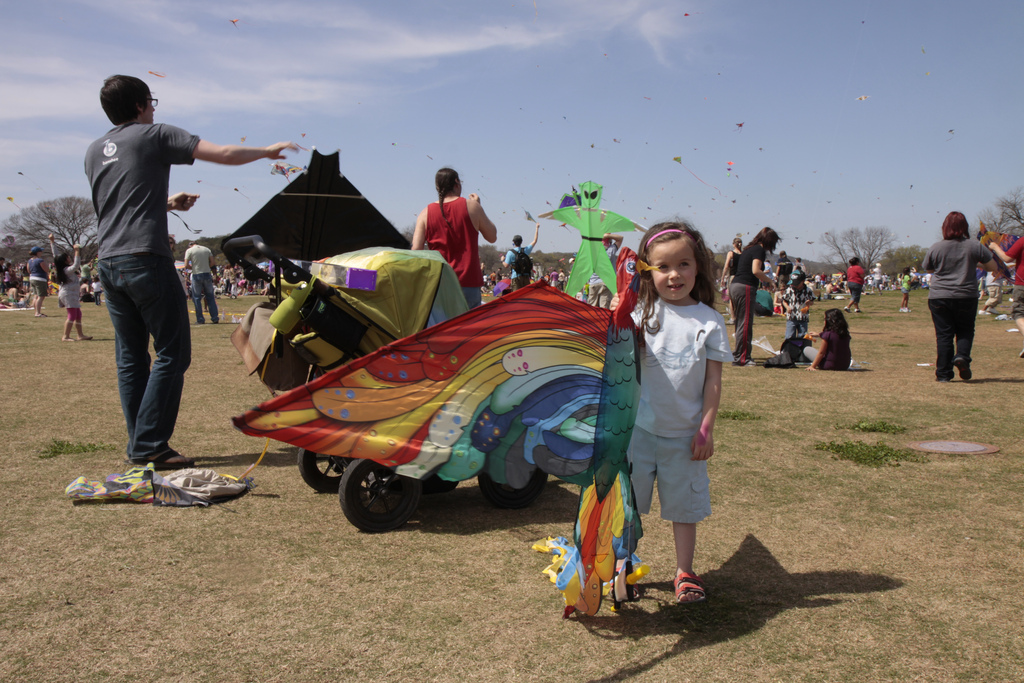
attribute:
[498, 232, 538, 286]
person — standing